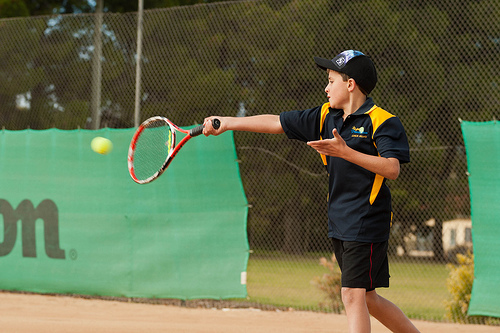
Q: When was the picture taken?
A: Daytime.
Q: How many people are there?
A: One.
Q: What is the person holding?
A: A tennis racquet.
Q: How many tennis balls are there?
A: One.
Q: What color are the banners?
A: Green.